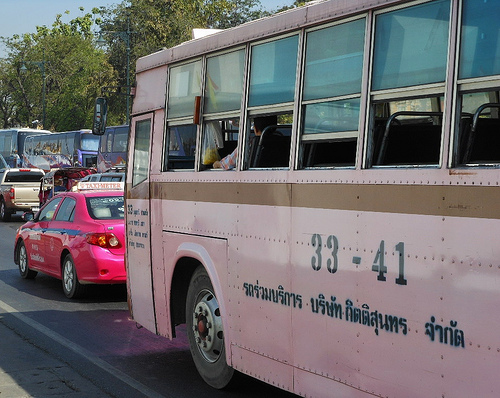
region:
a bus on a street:
[122, 2, 494, 395]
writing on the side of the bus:
[238, 269, 470, 365]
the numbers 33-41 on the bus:
[299, 224, 426, 292]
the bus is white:
[111, 0, 485, 396]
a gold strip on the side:
[121, 173, 498, 224]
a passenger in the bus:
[210, 112, 274, 171]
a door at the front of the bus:
[120, 112, 162, 338]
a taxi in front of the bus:
[15, 174, 130, 298]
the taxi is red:
[7, 176, 129, 297]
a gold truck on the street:
[0, 162, 51, 218]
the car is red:
[17, 185, 124, 283]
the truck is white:
[1, 165, 43, 212]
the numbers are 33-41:
[296, 225, 413, 292]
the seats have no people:
[291, 114, 497, 176]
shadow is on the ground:
[17, 303, 153, 385]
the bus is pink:
[126, 154, 476, 361]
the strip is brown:
[241, 180, 456, 213]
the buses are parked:
[19, 123, 123, 168]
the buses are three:
[9, 124, 123, 167]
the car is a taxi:
[41, 178, 130, 291]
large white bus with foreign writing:
[123, 3, 498, 393]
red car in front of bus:
[8, 180, 148, 298]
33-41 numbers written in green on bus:
[307, 228, 411, 290]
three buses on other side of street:
[1, 116, 128, 180]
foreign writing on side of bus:
[239, 277, 467, 348]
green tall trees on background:
[7, 2, 308, 125]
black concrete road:
[1, 216, 202, 389]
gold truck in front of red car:
[1, 168, 58, 226]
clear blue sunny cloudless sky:
[6, 1, 307, 58]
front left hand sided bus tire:
[171, 273, 251, 385]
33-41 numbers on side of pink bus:
[305, 226, 402, 282]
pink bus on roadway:
[116, 1, 496, 383]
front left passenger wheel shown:
[181, 265, 249, 382]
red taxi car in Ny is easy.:
[11, 176, 141, 300]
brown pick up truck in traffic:
[6, 160, 55, 222]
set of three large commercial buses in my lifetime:
[3, 115, 133, 183]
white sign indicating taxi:
[68, 178, 124, 199]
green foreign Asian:
[237, 276, 476, 351]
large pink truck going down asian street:
[110, 3, 497, 397]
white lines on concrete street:
[3, 286, 154, 391]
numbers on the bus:
[282, 235, 431, 292]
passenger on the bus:
[202, 109, 279, 177]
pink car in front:
[17, 185, 114, 300]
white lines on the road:
[4, 302, 149, 389]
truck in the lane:
[0, 160, 39, 218]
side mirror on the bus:
[91, 92, 108, 137]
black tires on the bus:
[181, 277, 232, 392]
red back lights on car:
[78, 225, 116, 251]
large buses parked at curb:
[0, 128, 119, 166]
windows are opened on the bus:
[213, 110, 491, 158]